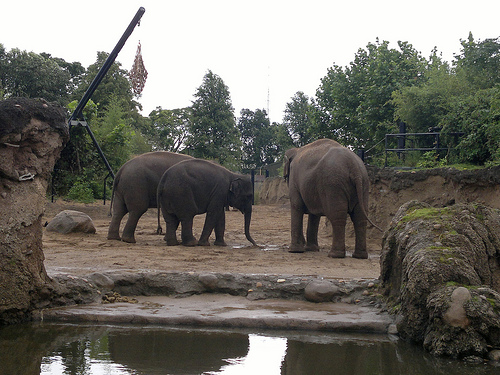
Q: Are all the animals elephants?
A: Yes, all the animals are elephants.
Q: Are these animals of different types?
A: No, all the animals are elephants.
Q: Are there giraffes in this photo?
A: No, there are no giraffes.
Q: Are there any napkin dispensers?
A: No, there are no napkin dispensers.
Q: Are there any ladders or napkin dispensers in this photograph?
A: No, there are no napkin dispensers or ladders.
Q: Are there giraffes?
A: No, there are no giraffes.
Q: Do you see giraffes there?
A: No, there are no giraffes.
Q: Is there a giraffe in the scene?
A: No, there are no giraffes.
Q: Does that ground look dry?
A: Yes, the ground is dry.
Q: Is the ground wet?
A: No, the ground is dry.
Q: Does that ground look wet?
A: No, the ground is dry.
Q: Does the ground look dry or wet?
A: The ground is dry.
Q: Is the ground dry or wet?
A: The ground is dry.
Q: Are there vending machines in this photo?
A: No, there are no vending machines.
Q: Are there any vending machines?
A: No, there are no vending machines.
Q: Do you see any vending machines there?
A: No, there are no vending machines.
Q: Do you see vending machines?
A: No, there are no vending machines.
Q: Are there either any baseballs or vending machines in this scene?
A: No, there are no vending machines or baseballs.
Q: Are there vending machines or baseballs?
A: No, there are no vending machines or baseballs.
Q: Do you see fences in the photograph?
A: Yes, there is a fence.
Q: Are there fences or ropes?
A: Yes, there is a fence.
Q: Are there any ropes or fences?
A: Yes, there is a fence.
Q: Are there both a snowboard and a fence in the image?
A: No, there is a fence but no snowboards.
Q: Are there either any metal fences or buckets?
A: Yes, there is a metal fence.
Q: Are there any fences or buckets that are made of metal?
A: Yes, the fence is made of metal.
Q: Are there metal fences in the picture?
A: Yes, there is a metal fence.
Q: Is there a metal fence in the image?
A: Yes, there is a metal fence.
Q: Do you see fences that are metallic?
A: Yes, there is a fence that is metallic.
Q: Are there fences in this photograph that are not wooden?
A: Yes, there is a metallic fence.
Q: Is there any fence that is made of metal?
A: Yes, there is a fence that is made of metal.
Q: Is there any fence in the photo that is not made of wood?
A: Yes, there is a fence that is made of metal.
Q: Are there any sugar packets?
A: No, there are no sugar packets.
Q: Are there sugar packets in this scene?
A: No, there are no sugar packets.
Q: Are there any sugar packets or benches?
A: No, there are no sugar packets or benches.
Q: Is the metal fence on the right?
A: Yes, the fence is on the right of the image.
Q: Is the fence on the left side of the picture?
A: No, the fence is on the right of the image.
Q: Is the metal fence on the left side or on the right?
A: The fence is on the right of the image.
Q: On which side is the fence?
A: The fence is on the right of the image.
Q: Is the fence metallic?
A: Yes, the fence is metallic.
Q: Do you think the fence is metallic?
A: Yes, the fence is metallic.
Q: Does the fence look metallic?
A: Yes, the fence is metallic.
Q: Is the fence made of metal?
A: Yes, the fence is made of metal.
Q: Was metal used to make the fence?
A: Yes, the fence is made of metal.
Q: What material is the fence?
A: The fence is made of metal.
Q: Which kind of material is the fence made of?
A: The fence is made of metal.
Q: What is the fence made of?
A: The fence is made of metal.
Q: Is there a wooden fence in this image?
A: No, there is a fence but it is metallic.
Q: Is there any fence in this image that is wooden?
A: No, there is a fence but it is metallic.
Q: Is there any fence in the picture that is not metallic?
A: No, there is a fence but it is metallic.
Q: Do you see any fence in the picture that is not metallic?
A: No, there is a fence but it is metallic.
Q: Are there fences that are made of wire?
A: No, there is a fence but it is made of metal.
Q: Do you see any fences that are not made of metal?
A: No, there is a fence but it is made of metal.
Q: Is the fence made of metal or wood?
A: The fence is made of metal.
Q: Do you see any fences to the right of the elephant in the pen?
A: Yes, there is a fence to the right of the elephant.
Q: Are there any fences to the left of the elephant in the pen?
A: No, the fence is to the right of the elephant.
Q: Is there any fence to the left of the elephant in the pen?
A: No, the fence is to the right of the elephant.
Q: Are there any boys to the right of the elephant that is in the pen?
A: No, there is a fence to the right of the elephant.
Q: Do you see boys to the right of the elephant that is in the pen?
A: No, there is a fence to the right of the elephant.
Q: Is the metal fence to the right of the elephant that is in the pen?
A: Yes, the fence is to the right of the elephant.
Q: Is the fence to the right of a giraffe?
A: No, the fence is to the right of the elephant.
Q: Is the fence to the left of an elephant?
A: No, the fence is to the right of an elephant.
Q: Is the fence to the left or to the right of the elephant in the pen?
A: The fence is to the right of the elephant.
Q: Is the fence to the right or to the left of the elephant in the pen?
A: The fence is to the right of the elephant.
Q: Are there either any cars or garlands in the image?
A: No, there are no cars or garlands.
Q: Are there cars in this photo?
A: No, there are no cars.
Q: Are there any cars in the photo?
A: No, there are no cars.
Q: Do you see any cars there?
A: No, there are no cars.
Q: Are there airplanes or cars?
A: No, there are no cars or airplanes.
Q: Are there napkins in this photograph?
A: No, there are no napkins.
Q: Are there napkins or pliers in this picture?
A: No, there are no napkins or pliers.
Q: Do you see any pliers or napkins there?
A: No, there are no napkins or pliers.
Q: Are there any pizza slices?
A: No, there are no pizza slices.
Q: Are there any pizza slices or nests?
A: No, there are no pizza slices or nests.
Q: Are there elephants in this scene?
A: Yes, there is an elephant.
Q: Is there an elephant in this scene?
A: Yes, there is an elephant.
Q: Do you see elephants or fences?
A: Yes, there is an elephant.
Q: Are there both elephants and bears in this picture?
A: No, there is an elephant but no bears.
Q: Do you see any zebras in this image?
A: No, there are no zebras.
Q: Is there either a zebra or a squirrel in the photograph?
A: No, there are no zebras or squirrels.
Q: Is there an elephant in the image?
A: Yes, there is an elephant.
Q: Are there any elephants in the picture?
A: Yes, there is an elephant.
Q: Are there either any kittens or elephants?
A: Yes, there is an elephant.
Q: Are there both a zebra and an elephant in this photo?
A: No, there is an elephant but no zebras.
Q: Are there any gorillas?
A: No, there are no gorillas.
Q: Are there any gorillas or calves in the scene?
A: No, there are no gorillas or calves.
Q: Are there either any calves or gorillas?
A: No, there are no gorillas or calves.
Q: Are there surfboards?
A: No, there are no surfboards.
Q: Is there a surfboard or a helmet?
A: No, there are no surfboards or helmets.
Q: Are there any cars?
A: No, there are no cars.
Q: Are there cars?
A: No, there are no cars.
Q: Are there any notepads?
A: No, there are no notepads.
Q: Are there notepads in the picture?
A: No, there are no notepads.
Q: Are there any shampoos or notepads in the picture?
A: No, there are no notepads or shampoos.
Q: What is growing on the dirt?
A: The moss is growing on the dirt.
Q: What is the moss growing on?
A: The moss is growing on the dirt.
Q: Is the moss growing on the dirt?
A: Yes, the moss is growing on the dirt.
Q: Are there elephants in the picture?
A: Yes, there is an elephant.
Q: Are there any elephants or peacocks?
A: Yes, there is an elephant.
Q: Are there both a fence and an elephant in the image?
A: Yes, there are both an elephant and a fence.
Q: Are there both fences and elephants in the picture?
A: Yes, there are both an elephant and a fence.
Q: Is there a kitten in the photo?
A: No, there are no kittens.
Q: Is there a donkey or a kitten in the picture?
A: No, there are no kittens or donkeys.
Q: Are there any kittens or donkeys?
A: No, there are no kittens or donkeys.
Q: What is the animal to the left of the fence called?
A: The animal is an elephant.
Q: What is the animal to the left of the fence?
A: The animal is an elephant.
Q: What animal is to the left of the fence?
A: The animal is an elephant.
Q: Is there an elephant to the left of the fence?
A: Yes, there is an elephant to the left of the fence.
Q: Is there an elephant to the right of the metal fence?
A: No, the elephant is to the left of the fence.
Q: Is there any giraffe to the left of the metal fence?
A: No, there is an elephant to the left of the fence.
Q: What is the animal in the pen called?
A: The animal is an elephant.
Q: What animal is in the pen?
A: The animal is an elephant.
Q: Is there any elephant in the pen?
A: Yes, there is an elephant in the pen.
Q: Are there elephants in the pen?
A: Yes, there is an elephant in the pen.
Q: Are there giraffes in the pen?
A: No, there is an elephant in the pen.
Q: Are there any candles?
A: No, there are no candles.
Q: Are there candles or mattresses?
A: No, there are no candles or mattresses.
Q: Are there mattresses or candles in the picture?
A: No, there are no candles or mattresses.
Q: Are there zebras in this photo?
A: No, there are no zebras.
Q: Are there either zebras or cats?
A: No, there are no zebras or cats.